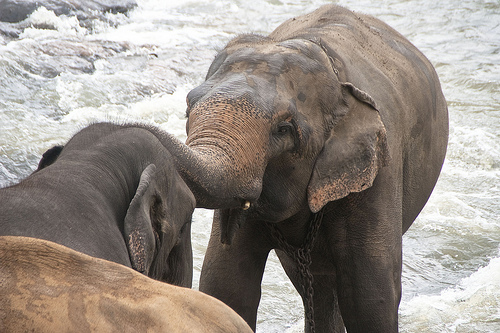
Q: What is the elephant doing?
A: Interacting with another elephant.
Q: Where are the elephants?
A: By some water.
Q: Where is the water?
A: Behind the elephants.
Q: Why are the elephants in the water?
A: To drink.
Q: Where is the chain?
A: Around the elephant's neck.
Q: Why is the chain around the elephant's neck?
A: To keep it in captivity.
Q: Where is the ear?
A: On the elephant.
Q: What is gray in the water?
A: The elephant.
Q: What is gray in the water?
A: The elephant.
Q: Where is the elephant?
A: In the water.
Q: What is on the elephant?
A: Trunk.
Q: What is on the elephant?
A: Tusk.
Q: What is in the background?
A: Water.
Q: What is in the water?
A: Waves.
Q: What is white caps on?
A: The water.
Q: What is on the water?
A: Froth.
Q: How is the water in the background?
A: Rushing.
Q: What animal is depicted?
A: Elephant.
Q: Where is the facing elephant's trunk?
A: Raised above another elephant.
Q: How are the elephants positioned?
A: Standing face to face.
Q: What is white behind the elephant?
A: Rushing water.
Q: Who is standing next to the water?
A: The elephant.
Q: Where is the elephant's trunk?
A: On the other elephant's head.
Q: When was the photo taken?
A: Daytime.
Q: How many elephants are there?
A: Three.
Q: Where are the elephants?
A: Near the water.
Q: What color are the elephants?
A: Gray.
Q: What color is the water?
A: White.